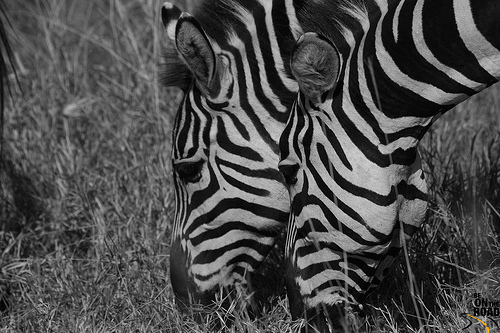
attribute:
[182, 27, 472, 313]
zebras — White, Black 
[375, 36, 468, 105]
stripes — Black, White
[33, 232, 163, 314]
grass — White Shot , Black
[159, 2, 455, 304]
zebras — Foal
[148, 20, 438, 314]
heads — two zebra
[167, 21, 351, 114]
ears — fuzzy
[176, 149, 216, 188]
eyes — black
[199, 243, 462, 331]
grasses — long 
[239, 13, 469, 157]
neck — striped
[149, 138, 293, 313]
face —  white part, zebra's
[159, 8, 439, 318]
zebra —  left, Eating Grass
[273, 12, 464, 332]
zebra —  right, ear fuzz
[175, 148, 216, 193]
eyes — black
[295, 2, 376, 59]
hair — black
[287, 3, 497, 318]
head — zebra's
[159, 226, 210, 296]
nose — black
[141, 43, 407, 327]
zebras — grazing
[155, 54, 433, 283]
zebra — grazing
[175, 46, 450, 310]
zebras — foraging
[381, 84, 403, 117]
neck — black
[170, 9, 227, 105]
ear — furry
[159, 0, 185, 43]
ear — shaped differently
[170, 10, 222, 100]
ear — shaped differently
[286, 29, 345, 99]
ear — shaped differently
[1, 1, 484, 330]
grass — rough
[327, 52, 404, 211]
stripes — white, Black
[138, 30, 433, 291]
zebra — Black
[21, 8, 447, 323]
grass — Black, white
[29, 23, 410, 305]
grass — Dry